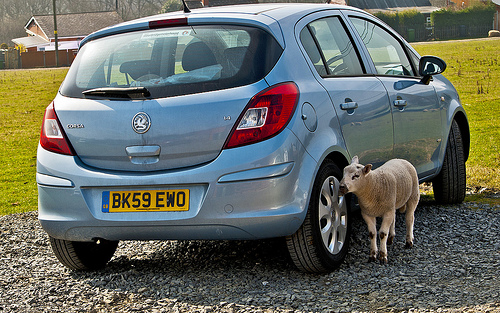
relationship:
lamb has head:
[336, 156, 419, 265] [338, 153, 373, 195]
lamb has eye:
[336, 156, 419, 265] [351, 172, 359, 179]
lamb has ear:
[336, 156, 419, 265] [363, 162, 373, 175]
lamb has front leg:
[336, 156, 419, 265] [377, 209, 394, 260]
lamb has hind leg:
[336, 156, 419, 265] [405, 188, 422, 245]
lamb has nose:
[336, 156, 419, 265] [340, 183, 347, 191]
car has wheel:
[40, 1, 469, 274] [287, 162, 353, 273]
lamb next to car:
[336, 156, 419, 265] [40, 1, 469, 274]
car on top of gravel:
[40, 1, 469, 274] [2, 190, 500, 312]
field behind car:
[0, 35, 499, 216] [40, 1, 469, 274]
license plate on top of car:
[102, 188, 190, 211] [40, 1, 469, 274]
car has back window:
[40, 1, 469, 274] [61, 23, 284, 101]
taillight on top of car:
[224, 81, 301, 156] [40, 1, 469, 274]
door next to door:
[294, 10, 392, 172] [342, 9, 443, 178]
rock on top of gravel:
[262, 279, 270, 287] [2, 190, 500, 312]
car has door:
[40, 1, 469, 274] [294, 10, 392, 172]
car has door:
[40, 1, 469, 274] [342, 9, 443, 178]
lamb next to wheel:
[336, 156, 419, 265] [287, 162, 353, 273]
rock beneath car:
[262, 279, 270, 287] [40, 1, 469, 274]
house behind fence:
[13, 10, 125, 50] [21, 49, 78, 66]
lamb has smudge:
[336, 156, 419, 265] [368, 230, 376, 241]